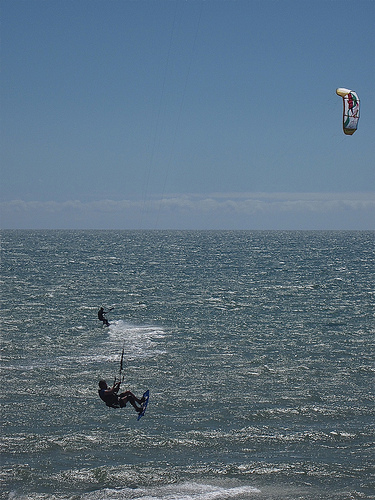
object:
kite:
[335, 86, 361, 136]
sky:
[0, 0, 373, 219]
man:
[98, 380, 146, 413]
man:
[98, 307, 115, 326]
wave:
[84, 481, 252, 500]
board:
[137, 389, 150, 421]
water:
[0, 224, 373, 500]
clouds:
[2, 181, 374, 232]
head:
[98, 379, 108, 389]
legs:
[122, 390, 145, 412]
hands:
[112, 383, 120, 391]